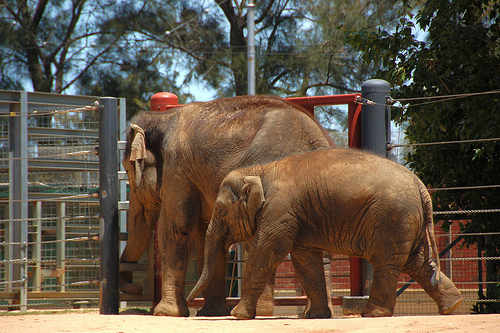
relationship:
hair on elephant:
[183, 96, 273, 125] [116, 95, 334, 316]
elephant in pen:
[185, 148, 465, 319] [1, 66, 498, 331]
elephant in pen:
[116, 95, 334, 316] [1, 66, 498, 331]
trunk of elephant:
[108, 162, 165, 298] [113, 78, 343, 313]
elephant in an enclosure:
[116, 95, 334, 316] [2, 87, 499, 318]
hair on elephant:
[243, 146, 380, 166] [181, 147, 467, 318]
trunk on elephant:
[185, 205, 234, 308] [181, 147, 467, 318]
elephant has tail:
[187, 159, 461, 306] [413, 186, 453, 284]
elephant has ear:
[185, 148, 465, 319] [248, 180, 295, 248]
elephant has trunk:
[116, 95, 334, 316] [114, 185, 161, 294]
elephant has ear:
[105, 66, 364, 293] [124, 119, 162, 214]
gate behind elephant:
[145, 92, 363, 308] [181, 147, 467, 318]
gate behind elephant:
[145, 92, 363, 308] [116, 95, 334, 316]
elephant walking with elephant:
[116, 95, 334, 316] [99, 87, 456, 318]